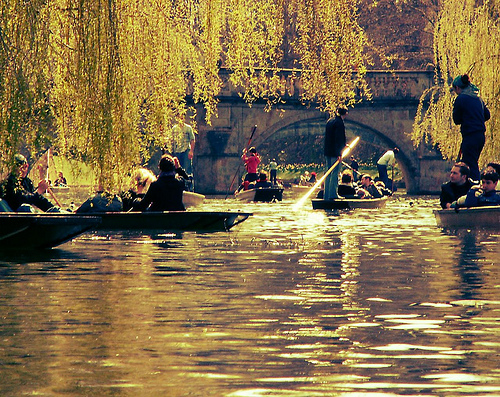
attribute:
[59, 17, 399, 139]
tree — large, hanging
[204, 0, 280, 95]
branches — hanging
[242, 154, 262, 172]
shirt — red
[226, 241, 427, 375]
river — lit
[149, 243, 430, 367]
water — calm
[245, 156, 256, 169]
jacket — red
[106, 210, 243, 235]
boat — green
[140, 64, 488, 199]
bridge — stone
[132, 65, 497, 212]
bridge — stone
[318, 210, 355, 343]
reflection — person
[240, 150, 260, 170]
top — pink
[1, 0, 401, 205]
tree — yellow, hanging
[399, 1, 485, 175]
tree — hanging, yellow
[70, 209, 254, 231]
boat — long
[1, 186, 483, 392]
water body — large, open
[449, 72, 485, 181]
person — standing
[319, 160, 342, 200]
jeans — long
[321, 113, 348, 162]
shirt — large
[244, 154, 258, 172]
coat — red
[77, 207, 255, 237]
boat — floating